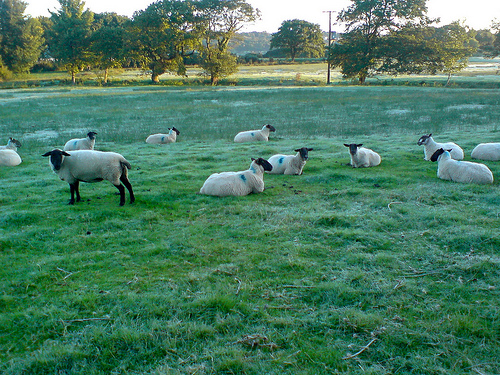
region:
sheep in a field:
[47, 43, 489, 350]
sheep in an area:
[79, 23, 492, 333]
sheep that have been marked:
[48, 58, 492, 275]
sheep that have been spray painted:
[37, 53, 483, 373]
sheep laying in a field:
[54, 75, 499, 304]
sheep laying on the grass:
[57, 51, 499, 294]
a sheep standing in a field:
[47, 68, 243, 282]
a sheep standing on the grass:
[37, 101, 248, 300]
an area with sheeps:
[61, 36, 471, 276]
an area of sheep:
[53, 106, 425, 290]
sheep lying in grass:
[203, 156, 268, 202]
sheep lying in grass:
[268, 147, 308, 173]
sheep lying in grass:
[343, 141, 381, 165]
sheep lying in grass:
[436, 155, 493, 190]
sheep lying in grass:
[417, 135, 465, 159]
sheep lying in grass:
[231, 124, 277, 144]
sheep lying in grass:
[143, 126, 175, 143]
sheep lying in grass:
[471, 142, 498, 160]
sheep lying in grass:
[2, 147, 22, 162]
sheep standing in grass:
[47, 147, 137, 205]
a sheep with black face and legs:
[40, 148, 139, 208]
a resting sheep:
[198, 155, 274, 199]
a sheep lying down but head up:
[264, 145, 318, 173]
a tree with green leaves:
[268, 18, 326, 62]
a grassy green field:
[1, 75, 497, 373]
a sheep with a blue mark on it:
[144, 125, 181, 146]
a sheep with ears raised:
[342, 140, 382, 167]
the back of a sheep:
[469, 140, 499, 160]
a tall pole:
[322, 8, 335, 85]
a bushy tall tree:
[42, 0, 98, 85]